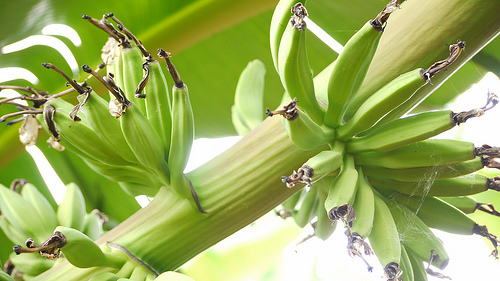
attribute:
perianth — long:
[371, 0, 403, 32]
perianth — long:
[428, 41, 464, 80]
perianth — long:
[455, 90, 497, 126]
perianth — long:
[160, 50, 185, 88]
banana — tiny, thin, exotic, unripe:
[325, 20, 384, 121]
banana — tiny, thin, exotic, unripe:
[277, 20, 325, 128]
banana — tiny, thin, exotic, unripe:
[167, 88, 195, 184]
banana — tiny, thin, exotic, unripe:
[121, 103, 169, 183]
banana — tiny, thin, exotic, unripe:
[374, 138, 476, 170]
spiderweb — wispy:
[375, 157, 459, 243]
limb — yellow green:
[22, 2, 498, 279]